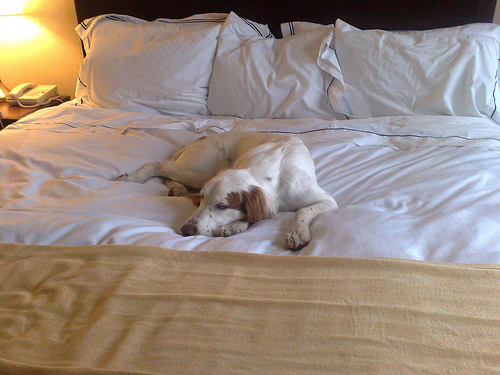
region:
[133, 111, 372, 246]
dog on the bed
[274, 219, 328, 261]
paw of the dog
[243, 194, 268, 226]
brown ear of the dog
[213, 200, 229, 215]
eye of the dog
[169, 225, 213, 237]
nose of the dog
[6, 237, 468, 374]
blanket at end of bed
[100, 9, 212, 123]
pillow at top of bed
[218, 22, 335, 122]
pillow at top of bed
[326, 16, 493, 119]
pillow at top of bed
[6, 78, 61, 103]
phone on nightstand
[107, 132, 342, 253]
A white and brown dog sleeping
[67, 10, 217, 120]
A fluffy white pillow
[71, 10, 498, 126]
Three white pillows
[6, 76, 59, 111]
A white phone on a bedside table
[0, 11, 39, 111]
A lamp that is turned on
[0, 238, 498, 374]
A tan blanket on a bed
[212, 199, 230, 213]
An eye of a dog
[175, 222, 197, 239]
A black nose of a dog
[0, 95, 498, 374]
A large bed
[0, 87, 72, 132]
A brown wooden bedside table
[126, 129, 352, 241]
brown and white dog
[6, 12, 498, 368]
white and brown dog on bed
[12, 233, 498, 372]
brown blanket on end of bed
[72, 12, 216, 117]
fluffy white pillow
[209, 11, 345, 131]
white pillow with blue pin striping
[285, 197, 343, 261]
front paw of dog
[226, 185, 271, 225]
brown ear of dog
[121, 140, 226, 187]
hind leg of dog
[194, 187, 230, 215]
closed eyes of dog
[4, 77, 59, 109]
white corded telephone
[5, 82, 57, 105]
this is a white telephone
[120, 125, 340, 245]
the dog is laying down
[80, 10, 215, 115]
the pillow is white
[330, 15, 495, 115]
a white pillow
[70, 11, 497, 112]
three pillows on a bed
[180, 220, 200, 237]
the nose of a dog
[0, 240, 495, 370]
a brown sheet on a bed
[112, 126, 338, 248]
the dog is on a bed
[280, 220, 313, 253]
the paw of a dog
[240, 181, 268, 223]
the ear of a dog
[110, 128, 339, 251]
a white and brown dog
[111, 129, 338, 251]
a dog on a bed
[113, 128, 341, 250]
a sleeping dog on a bed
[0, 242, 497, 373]
a brown blanket on a bed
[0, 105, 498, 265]
a white comforter on the bed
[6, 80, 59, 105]
a phone on the bedside table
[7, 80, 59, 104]
a white phone on the table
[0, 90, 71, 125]
a table beside the bed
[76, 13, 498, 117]
pillows on the bed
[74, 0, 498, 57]
the headboard of the bed